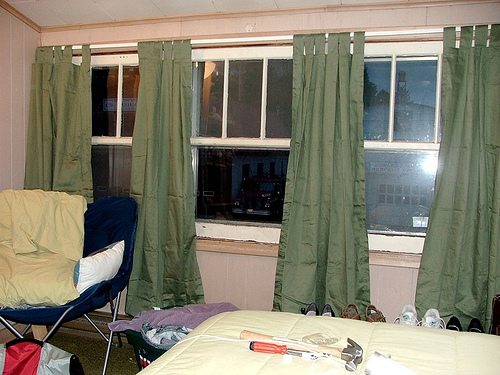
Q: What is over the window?
A: Curtain rod.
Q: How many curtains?
A: Four.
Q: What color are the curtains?
A: Green.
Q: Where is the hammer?
A: On bed.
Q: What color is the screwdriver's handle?
A: Red and black.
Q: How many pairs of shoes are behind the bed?
A: Four.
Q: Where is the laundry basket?
A: Floor.